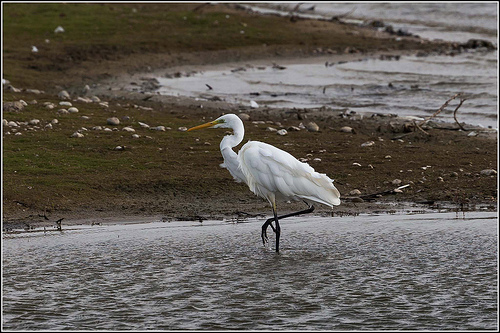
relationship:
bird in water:
[183, 103, 341, 268] [228, 282, 268, 305]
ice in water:
[314, 297, 337, 313] [228, 282, 268, 305]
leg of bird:
[262, 208, 284, 254] [183, 103, 341, 268]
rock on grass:
[359, 135, 382, 158] [125, 161, 149, 184]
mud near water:
[374, 197, 404, 209] [228, 282, 268, 305]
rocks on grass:
[359, 135, 382, 158] [125, 161, 149, 184]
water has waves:
[228, 282, 268, 305] [423, 295, 449, 317]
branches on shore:
[437, 93, 473, 124] [431, 137, 464, 152]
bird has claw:
[183, 103, 341, 268] [257, 218, 275, 237]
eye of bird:
[213, 112, 224, 126] [183, 103, 341, 268]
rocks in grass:
[359, 135, 382, 158] [125, 161, 149, 184]